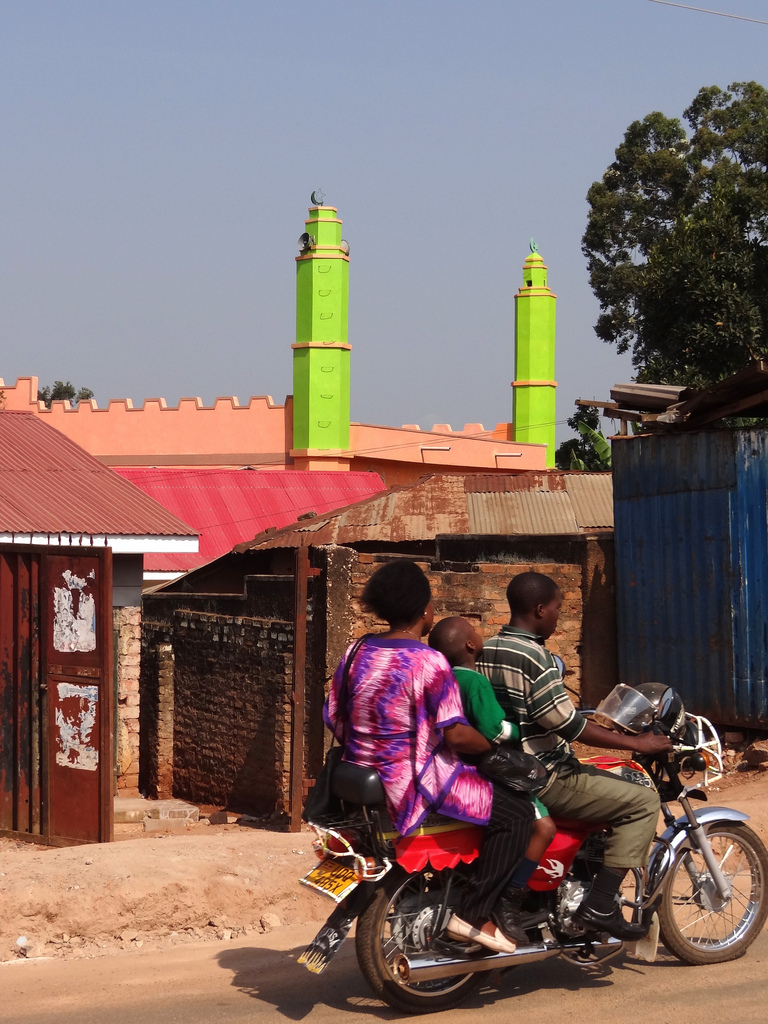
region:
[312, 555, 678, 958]
Three people riding on a motorcycle.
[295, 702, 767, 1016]
The motorcycle is red.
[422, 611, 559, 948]
A young boy on a motorcycle.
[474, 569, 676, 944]
A man riding on a motorcycle.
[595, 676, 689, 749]
A motorcycle helmet.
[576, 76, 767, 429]
A big green tree.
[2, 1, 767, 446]
A clear blue sky.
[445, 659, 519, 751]
A green shirt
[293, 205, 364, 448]
Green post on building top.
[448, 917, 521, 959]
Person wearing loafer on food.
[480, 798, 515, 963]
Person wearing black pants.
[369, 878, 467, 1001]
Back wheel on bike is black.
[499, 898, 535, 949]
Person wearing black shoes.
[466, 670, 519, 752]
Person wearing green shirt.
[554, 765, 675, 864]
Person wearing khaki pants.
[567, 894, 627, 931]
Person wearing black shoe.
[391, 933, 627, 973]
Silver exhaust pipe on bike.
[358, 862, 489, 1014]
A tire on a vehicle.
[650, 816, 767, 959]
A tire on a vehicle.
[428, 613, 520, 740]
A person is sitting down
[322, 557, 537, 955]
A person sitting down.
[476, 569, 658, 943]
A person sitting down.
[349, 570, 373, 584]
A brick in a building.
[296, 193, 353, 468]
the tower is green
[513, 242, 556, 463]
the tower is green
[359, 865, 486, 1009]
wheel of a motorcycle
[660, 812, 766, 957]
wheel of a motorcycle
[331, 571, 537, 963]
person on a motorcycle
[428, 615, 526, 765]
person on a motorcycle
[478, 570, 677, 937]
person on a motorcycle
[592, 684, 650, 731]
visor of a helmet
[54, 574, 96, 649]
the paint is white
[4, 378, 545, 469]
the wall is orange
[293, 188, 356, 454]
tall green cylinders with gold trim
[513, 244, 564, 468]
tall green cylinders with gold trim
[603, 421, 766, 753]
blue metal garbage receptacle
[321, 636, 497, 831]
purple pink and white outfit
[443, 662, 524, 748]
green shirt with white strip on sleeves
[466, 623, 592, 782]
green and brown shirt with white stripes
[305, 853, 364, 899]
yellow license plate with black lettering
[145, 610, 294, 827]
dark brick wall on side of building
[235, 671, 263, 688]
A brick in a wall.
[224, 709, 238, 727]
A brick in a wall.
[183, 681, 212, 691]
A brick in a wall.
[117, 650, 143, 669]
A brick in a wall.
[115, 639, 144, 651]
A brick in a wall.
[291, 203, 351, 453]
The green tower with speakers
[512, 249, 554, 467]
The green tower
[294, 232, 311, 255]
The speaker on the green tower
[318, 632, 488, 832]
The pink and purple shirt on the woman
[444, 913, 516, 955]
The white loafer on the woman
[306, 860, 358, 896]
The yellow plate on the bike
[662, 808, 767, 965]
The front tire of the bike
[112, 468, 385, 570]
The bright red roof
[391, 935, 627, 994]
The exhaust on the bike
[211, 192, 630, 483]
the towers are tall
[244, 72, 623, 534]
the tower are green and gold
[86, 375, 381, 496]
the building is pink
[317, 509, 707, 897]
the people are riding a motorcycle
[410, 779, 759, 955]
the motorbike is red